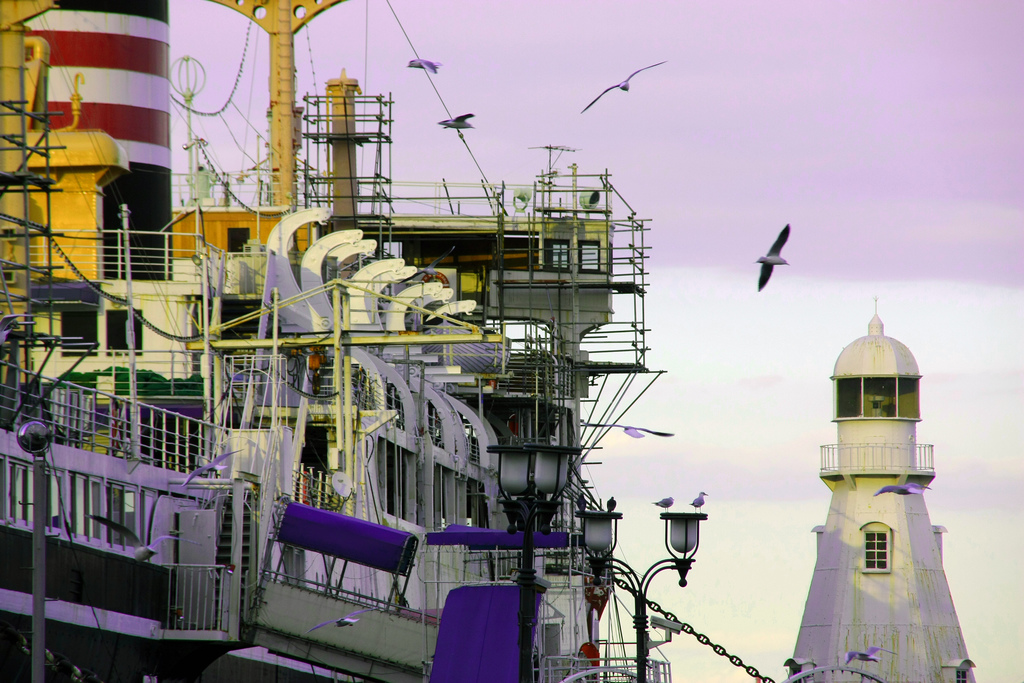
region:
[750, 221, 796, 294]
A sea gull in the air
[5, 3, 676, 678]
A large ship near a light house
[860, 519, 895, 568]
A window on a lighthouse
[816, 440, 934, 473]
A railing on a lighthouse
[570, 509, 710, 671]
A light pole near a ship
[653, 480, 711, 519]
Birds sitting on a light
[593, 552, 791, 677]
A chain to a boat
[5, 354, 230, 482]
Railing on a ship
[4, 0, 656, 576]
superstructure of ship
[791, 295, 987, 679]
white lighthouse with upper walkway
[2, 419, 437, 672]
walkway onto a ship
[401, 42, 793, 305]
four flying seagulls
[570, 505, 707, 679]
two lights on a lampost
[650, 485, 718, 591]
two birds standing on an outdoor light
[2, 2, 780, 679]
chain connecting ship to dock is behind lampost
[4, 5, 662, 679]
yellow metal tower rising from ship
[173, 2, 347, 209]
chain attached to yellow metal tower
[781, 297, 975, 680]
Lighthouse is white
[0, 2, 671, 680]
The ship is big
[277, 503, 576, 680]
The entrance is purple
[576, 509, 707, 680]
The lamp is in front of the ship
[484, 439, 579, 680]
The lamp is in front of the ship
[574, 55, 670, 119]
The bird is flying in the sky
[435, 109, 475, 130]
The bird is flying in the sky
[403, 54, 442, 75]
The bird is flying in the sky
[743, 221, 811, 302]
Bird flying in the sky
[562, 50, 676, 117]
Bird flying in the sky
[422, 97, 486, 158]
Bird flying in the sky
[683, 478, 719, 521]
bird standing on the light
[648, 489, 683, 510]
bird standing on the light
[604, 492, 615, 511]
bird standing on the light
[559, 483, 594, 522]
bird standing on the light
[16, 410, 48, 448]
light on side of the boat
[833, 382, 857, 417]
a window on a building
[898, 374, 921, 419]
a window on a building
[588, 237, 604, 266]
a window on a building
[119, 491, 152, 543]
a window on a building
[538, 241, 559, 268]
a window on a building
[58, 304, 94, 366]
a window on a building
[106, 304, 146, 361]
a window on a building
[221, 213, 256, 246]
a window on a building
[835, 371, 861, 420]
a window on a building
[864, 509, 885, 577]
a window on a building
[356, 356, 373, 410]
a window on a building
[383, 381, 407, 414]
a window on a building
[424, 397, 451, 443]
a window on a building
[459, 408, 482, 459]
a window on a building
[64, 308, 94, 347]
a window on a building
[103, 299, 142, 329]
a window on a building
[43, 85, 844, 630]
this is a harbor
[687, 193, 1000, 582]
the light house is white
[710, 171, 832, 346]
this is a bird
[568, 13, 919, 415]
the birds are in flight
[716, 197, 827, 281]
a bird is flying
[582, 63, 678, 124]
a bird is flying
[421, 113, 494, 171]
a bird is flying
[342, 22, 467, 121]
a bird is flyinga bird is flying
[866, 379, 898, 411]
a window on a building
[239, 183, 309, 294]
a window on a building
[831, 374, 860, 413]
a window on a building